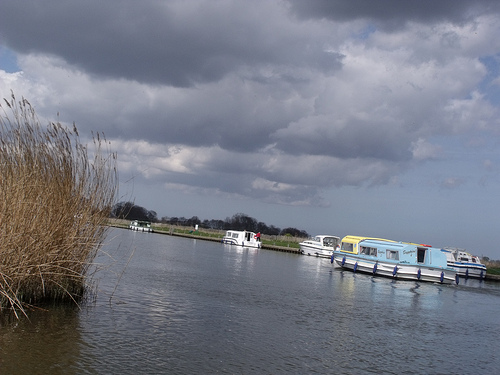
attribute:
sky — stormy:
[21, 18, 486, 243]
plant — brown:
[9, 114, 99, 304]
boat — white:
[201, 226, 266, 271]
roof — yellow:
[335, 234, 423, 254]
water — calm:
[99, 274, 448, 370]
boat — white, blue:
[454, 247, 488, 284]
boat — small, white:
[221, 229, 262, 248]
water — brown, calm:
[1, 223, 499, 374]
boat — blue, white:
[331, 238, 457, 284]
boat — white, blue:
[444, 250, 484, 278]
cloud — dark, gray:
[2, 1, 366, 90]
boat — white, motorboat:
[297, 234, 339, 257]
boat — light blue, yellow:
[337, 230, 458, 291]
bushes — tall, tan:
[0, 85, 135, 327]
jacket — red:
[253, 230, 263, 240]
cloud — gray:
[273, 106, 419, 166]